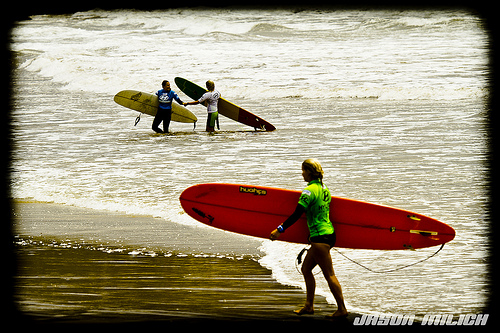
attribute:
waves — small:
[83, 19, 429, 41]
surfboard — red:
[179, 180, 453, 250]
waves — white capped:
[17, 12, 494, 111]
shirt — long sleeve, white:
[185, 91, 222, 115]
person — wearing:
[274, 156, 351, 314]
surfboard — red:
[172, 178, 459, 258]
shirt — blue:
[151, 99, 211, 124]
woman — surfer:
[267, 155, 350, 321]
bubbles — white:
[31, 36, 498, 285]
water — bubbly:
[16, 10, 487, 325]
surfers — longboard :
[102, 65, 459, 327]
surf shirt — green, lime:
[297, 179, 334, 236]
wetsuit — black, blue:
[152, 90, 183, 132]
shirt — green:
[297, 179, 336, 239]